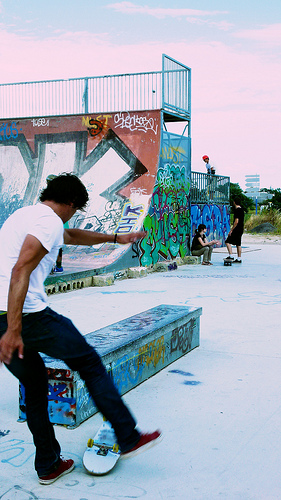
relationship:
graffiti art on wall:
[135, 164, 193, 266] [1, 106, 193, 288]